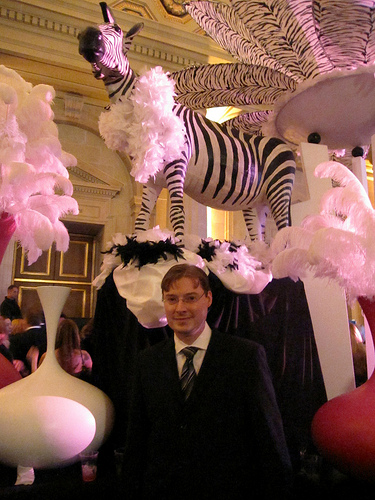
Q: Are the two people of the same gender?
A: No, they are both male and female.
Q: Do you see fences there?
A: No, there are no fences.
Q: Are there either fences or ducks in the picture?
A: No, there are no fences or ducks.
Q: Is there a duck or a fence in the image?
A: No, there are no fences or ducks.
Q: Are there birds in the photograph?
A: No, there are no birds.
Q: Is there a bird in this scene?
A: No, there are no birds.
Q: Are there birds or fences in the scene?
A: No, there are no birds or fences.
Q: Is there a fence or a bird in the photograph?
A: No, there are no birds or fences.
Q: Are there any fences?
A: No, there are no fences.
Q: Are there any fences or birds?
A: No, there are no fences or birds.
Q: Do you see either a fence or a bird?
A: No, there are no fences or birds.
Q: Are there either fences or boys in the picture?
A: No, there are no fences or boys.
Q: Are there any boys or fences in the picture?
A: No, there are no fences or boys.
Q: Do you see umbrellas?
A: No, there are no umbrellas.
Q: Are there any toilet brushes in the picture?
A: No, there are no toilet brushes.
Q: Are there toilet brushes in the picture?
A: No, there are no toilet brushes.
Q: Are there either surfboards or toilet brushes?
A: No, there are no toilet brushes or surfboards.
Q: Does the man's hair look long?
A: Yes, the hair is long.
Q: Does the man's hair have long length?
A: Yes, the hair is long.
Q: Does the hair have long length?
A: Yes, the hair is long.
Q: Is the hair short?
A: No, the hair is long.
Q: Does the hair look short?
A: No, the hair is long.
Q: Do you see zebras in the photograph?
A: Yes, there is a zebra.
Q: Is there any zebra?
A: Yes, there is a zebra.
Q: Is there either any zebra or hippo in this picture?
A: Yes, there is a zebra.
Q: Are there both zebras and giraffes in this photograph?
A: No, there is a zebra but no giraffes.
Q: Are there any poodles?
A: No, there are no poodles.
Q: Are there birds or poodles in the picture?
A: No, there are no poodles or birds.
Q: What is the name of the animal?
A: The animal is a zebra.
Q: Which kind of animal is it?
A: The animal is a zebra.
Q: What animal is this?
A: This is a zebra.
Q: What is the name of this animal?
A: This is a zebra.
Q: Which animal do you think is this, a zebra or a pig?
A: This is a zebra.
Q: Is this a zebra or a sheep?
A: This is a zebra.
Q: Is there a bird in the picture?
A: No, there are no birds.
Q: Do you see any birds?
A: No, there are no birds.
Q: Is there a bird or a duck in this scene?
A: No, there are no birds or ducks.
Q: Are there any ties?
A: Yes, there is a tie.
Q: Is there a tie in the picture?
A: Yes, there is a tie.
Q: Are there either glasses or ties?
A: Yes, there is a tie.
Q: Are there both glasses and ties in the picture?
A: Yes, there are both a tie and glasses.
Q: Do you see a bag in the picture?
A: No, there are no bags.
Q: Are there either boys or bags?
A: No, there are no bags or boys.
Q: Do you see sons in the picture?
A: No, there are no sons.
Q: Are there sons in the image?
A: No, there are no sons.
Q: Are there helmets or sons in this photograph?
A: No, there are no sons or helmets.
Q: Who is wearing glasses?
A: The man is wearing glasses.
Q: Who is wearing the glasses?
A: The man is wearing glasses.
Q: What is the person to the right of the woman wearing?
A: The man is wearing glasses.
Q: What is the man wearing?
A: The man is wearing glasses.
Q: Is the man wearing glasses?
A: Yes, the man is wearing glasses.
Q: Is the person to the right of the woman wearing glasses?
A: Yes, the man is wearing glasses.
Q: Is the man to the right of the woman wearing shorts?
A: No, the man is wearing glasses.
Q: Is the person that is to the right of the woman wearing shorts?
A: No, the man is wearing glasses.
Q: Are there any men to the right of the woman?
A: Yes, there is a man to the right of the woman.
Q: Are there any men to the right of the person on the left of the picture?
A: Yes, there is a man to the right of the woman.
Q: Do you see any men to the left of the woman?
A: No, the man is to the right of the woman.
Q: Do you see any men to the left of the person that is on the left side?
A: No, the man is to the right of the woman.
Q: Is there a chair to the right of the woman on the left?
A: No, there is a man to the right of the woman.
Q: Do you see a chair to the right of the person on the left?
A: No, there is a man to the right of the woman.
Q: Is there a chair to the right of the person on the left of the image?
A: No, there is a man to the right of the woman.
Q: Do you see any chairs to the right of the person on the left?
A: No, there is a man to the right of the woman.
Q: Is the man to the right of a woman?
A: Yes, the man is to the right of a woman.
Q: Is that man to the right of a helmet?
A: No, the man is to the right of a woman.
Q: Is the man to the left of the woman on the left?
A: No, the man is to the right of the woman.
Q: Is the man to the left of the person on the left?
A: No, the man is to the right of the woman.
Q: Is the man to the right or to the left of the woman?
A: The man is to the right of the woman.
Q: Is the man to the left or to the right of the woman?
A: The man is to the right of the woman.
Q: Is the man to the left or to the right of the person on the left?
A: The man is to the right of the woman.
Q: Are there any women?
A: Yes, there is a woman.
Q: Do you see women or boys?
A: Yes, there is a woman.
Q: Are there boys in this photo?
A: No, there are no boys.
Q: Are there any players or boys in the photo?
A: No, there are no boys or players.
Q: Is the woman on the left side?
A: Yes, the woman is on the left of the image.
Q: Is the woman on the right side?
A: No, the woman is on the left of the image.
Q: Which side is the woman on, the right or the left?
A: The woman is on the left of the image.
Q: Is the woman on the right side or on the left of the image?
A: The woman is on the left of the image.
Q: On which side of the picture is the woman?
A: The woman is on the left of the image.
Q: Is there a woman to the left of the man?
A: Yes, there is a woman to the left of the man.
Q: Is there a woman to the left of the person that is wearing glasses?
A: Yes, there is a woman to the left of the man.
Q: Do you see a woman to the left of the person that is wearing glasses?
A: Yes, there is a woman to the left of the man.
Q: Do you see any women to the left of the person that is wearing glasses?
A: Yes, there is a woman to the left of the man.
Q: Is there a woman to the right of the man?
A: No, the woman is to the left of the man.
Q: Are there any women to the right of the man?
A: No, the woman is to the left of the man.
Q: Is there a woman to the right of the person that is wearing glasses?
A: No, the woman is to the left of the man.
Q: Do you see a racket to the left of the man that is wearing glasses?
A: No, there is a woman to the left of the man.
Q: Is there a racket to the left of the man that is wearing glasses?
A: No, there is a woman to the left of the man.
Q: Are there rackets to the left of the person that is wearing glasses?
A: No, there is a woman to the left of the man.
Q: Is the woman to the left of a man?
A: Yes, the woman is to the left of a man.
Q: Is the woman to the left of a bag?
A: No, the woman is to the left of a man.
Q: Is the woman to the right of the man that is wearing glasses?
A: No, the woman is to the left of the man.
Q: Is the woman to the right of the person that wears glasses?
A: No, the woman is to the left of the man.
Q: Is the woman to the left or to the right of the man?
A: The woman is to the left of the man.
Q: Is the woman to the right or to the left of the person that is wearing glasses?
A: The woman is to the left of the man.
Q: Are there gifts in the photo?
A: No, there are no gifts.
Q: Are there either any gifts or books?
A: No, there are no gifts or books.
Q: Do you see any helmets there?
A: No, there are no helmets.